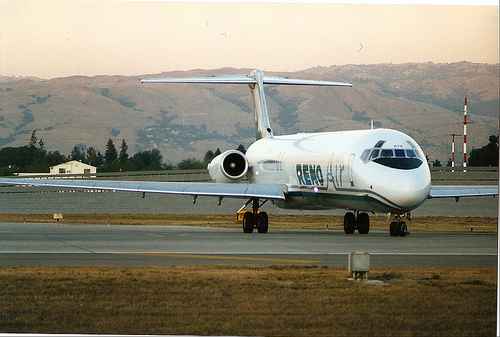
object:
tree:
[104, 137, 118, 163]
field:
[0, 264, 497, 337]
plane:
[0, 69, 499, 238]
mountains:
[0, 67, 499, 166]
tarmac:
[0, 222, 496, 267]